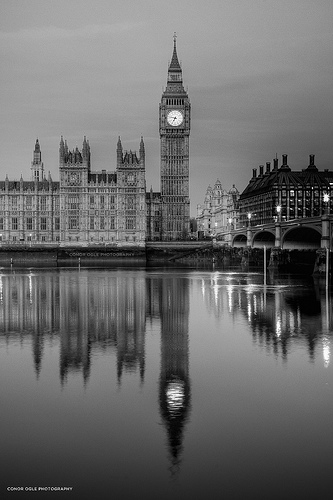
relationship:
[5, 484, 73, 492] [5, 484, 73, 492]
label of label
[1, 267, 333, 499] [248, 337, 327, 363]
water has ripples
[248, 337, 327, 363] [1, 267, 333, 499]
ripples in water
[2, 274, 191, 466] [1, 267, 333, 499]
reflection on water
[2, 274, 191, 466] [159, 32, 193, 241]
reflection of clocktower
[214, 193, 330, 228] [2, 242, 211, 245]
lights on street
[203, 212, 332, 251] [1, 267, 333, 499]
bridge over water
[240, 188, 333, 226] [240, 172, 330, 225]
windows in rows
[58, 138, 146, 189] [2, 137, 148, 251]
towers of buildings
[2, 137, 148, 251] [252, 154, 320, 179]
buildings with chimney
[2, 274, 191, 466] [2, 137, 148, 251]
reflection of buildings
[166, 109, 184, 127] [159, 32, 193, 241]
clock on clocktower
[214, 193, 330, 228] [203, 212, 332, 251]
lights on bridge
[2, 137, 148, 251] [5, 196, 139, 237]
buildings have windows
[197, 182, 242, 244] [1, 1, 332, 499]
building in london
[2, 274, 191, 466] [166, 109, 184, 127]
reflection of clock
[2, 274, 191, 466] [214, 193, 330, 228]
reflection of lights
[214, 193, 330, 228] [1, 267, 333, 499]
lights on water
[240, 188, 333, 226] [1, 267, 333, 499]
windows by water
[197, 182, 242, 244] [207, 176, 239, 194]
building with domes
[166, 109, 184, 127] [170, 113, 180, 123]
clock has face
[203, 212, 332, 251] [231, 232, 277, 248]
bridge has arches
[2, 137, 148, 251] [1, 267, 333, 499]
buildings on edge of water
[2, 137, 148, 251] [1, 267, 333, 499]
buildings along water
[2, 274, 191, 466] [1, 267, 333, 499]
reflection over water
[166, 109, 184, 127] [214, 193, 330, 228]
clock with lights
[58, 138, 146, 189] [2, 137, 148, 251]
towers between buildings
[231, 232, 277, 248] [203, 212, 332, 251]
arches on bridge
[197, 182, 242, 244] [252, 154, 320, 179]
building with chimney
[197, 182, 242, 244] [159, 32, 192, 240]
building with clocktower